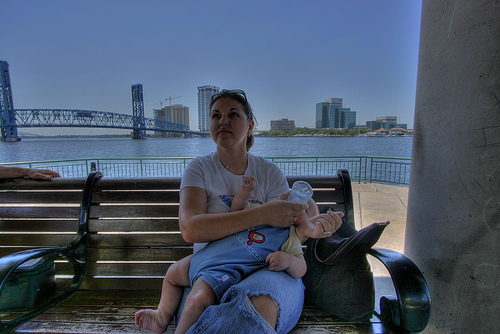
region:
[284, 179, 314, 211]
baby bottle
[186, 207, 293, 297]
blue baby onesie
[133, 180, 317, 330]
baby having a bottle in mom's arms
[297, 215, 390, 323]
black women's purse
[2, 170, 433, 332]
long wooden bench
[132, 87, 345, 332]
woman feeding her baby a bottle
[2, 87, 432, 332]
woman sitting on a bench feeding her baby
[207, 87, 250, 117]
black sunglasses on woman's head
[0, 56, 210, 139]
metal bridge over body of water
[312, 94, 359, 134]
tall buildings across the water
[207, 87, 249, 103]
the woman has glasses on her head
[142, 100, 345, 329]
the woman is holding a baby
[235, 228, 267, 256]
the baby's dress has a graphic print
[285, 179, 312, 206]
the woman is holding a baby bottle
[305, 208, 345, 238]
the woman has her fingers curled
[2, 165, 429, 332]
the woman is sitting on a bench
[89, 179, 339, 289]
the bench is made of wood boards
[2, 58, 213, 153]
a bridge is in the background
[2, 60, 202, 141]
the bridge is made of metal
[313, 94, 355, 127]
a building is in the distance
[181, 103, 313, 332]
a woman feeding a baby a bottle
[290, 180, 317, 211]
the bottle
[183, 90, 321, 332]
a woman holding a baby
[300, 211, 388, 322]
the purse of the lady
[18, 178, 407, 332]
a wooden bench the lady is sitting on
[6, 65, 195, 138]
a blue bridge over the water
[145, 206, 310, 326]
a baby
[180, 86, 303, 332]
a lady with a hole in her jeans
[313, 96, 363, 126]
a building in the background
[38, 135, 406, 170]
water behind the lady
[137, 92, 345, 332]
the woman is feeding a baby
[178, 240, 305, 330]
the woman is wearing jeans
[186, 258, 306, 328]
the jeans are blue in color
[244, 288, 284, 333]
the jeans have a tear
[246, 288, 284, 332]
the jean is torn at the knee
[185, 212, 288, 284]
the baby is wearing a blue dress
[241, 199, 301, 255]
the baby is wearing a short sleeve shirt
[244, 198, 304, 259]
the shirt is yellow in color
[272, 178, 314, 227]
the woman is holding a baby bottle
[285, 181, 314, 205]
the bottle is made of plastic